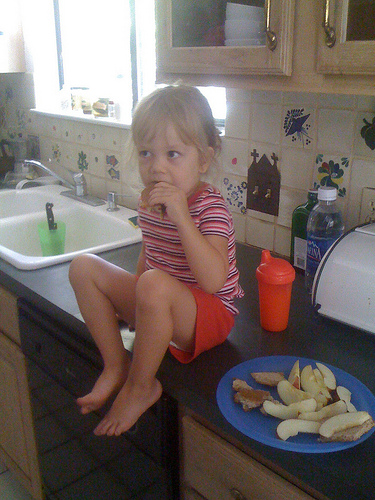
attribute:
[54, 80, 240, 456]
girl — barefoot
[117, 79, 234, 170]
hair — blonde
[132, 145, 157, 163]
eye — brown, open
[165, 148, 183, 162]
eye — brown, open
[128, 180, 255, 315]
shirt — striped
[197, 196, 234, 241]
sleeve — short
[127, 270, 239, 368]
shorts — orange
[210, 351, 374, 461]
plate — round, blue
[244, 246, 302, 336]
cup — orange